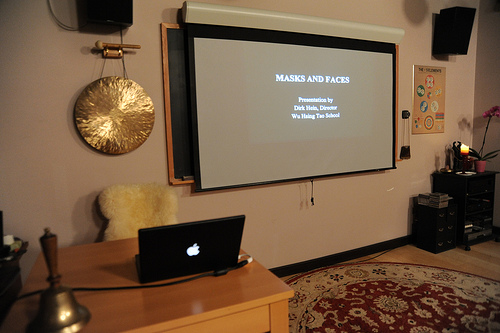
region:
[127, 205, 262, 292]
back side of laptop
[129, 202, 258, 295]
black laptop on desk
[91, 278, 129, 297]
black power cord of lap top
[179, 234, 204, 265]
white logo on lap top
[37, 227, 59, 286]
wooden handle of bell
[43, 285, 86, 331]
golden bell on desk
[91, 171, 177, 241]
white fuzzy chair by desk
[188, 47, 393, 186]
large white projector screen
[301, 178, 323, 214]
black handle of screen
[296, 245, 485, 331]
large red and white rug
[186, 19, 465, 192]
a screen on the wall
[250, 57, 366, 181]
some writing on a screen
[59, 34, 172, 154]
a hanging that is gold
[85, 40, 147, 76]
the string on a wall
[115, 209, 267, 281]
a small apple laptop computer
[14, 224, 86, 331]
a large handheld bell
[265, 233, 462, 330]
a large circular rug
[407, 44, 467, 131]
a large poster on the wall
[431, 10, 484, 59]
a black speaker on the wall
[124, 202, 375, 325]
the computer is black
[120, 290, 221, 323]
the desk is made of wood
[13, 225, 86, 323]
the bell is gold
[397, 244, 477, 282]
the ground is made of wood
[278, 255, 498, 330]
An area rug on the floor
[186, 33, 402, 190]
A white projector screen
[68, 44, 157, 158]
A hanging gold plate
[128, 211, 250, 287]
A black Apple laptop computer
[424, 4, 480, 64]
A black speaker on the wall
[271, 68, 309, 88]
The word "MASKS" on the screen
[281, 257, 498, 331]
The area rug is round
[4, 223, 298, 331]
A brown and wooden desk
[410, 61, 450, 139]
A poster on the wall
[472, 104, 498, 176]
Pink flower in a pink vase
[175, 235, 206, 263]
apple logo on the laptop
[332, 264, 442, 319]
rug on the floor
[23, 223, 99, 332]
bell on the desk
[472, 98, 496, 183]
plant on the stand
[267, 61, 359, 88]
masks and faces on the screen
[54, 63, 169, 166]
gold circle decoration on the wall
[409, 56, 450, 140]
poster on the wall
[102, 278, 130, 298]
wire on the desk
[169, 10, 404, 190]
A large screen hangs on the wall.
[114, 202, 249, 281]
A laptop is open on the desk.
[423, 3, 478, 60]
A speaker hangs on the wall.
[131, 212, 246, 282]
black laptop on table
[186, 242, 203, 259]
white apple on laptop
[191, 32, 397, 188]
large white projector screen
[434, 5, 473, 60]
black speaker on wall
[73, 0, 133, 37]
black speaker on wall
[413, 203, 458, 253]
small black filing cabinet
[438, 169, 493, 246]
small black book shelf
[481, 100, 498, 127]
large dark pink flower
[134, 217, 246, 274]
the computer is black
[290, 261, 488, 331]
the rug is on the floor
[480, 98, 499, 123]
the flower is pink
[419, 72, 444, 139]
stickers are on the board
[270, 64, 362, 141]
the words are on the screen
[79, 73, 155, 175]
the intrument is golden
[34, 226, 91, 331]
the bell is on the desk